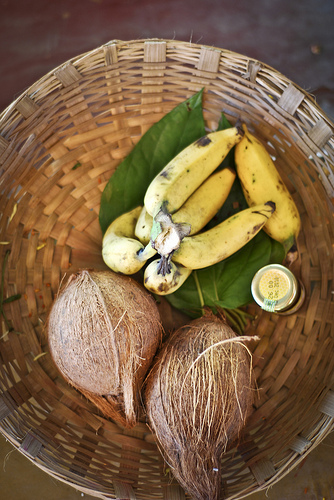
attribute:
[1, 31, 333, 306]
basket — brown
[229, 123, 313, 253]
banana — yellow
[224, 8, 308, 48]
table — red, grey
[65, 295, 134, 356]
brown — coconuts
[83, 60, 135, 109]
woven — basket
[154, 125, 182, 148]
leaves — green